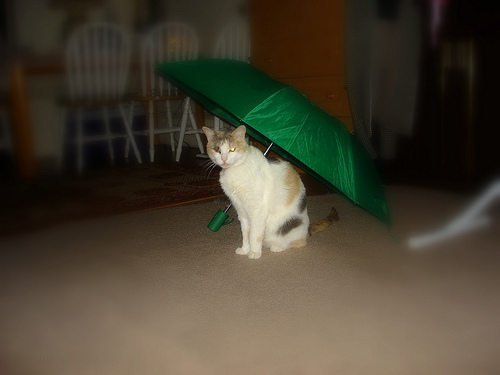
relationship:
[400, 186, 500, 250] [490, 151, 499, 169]
front leg of board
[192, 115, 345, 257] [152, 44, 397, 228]
cat under umbrella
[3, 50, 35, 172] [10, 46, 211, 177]
end of dining table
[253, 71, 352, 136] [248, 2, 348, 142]
chest of chest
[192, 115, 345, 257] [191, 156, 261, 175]
cat has whiskers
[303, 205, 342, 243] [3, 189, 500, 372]
tail on rug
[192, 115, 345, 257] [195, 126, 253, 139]
cat has ears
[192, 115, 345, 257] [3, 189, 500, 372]
cat on rug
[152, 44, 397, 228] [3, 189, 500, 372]
umbrella on rug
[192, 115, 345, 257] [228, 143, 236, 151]
cat has eye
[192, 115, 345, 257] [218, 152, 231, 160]
cat has nose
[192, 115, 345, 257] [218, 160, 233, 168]
cat has mouth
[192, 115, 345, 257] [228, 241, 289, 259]
cat has paws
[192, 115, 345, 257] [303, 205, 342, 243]
cat has tail